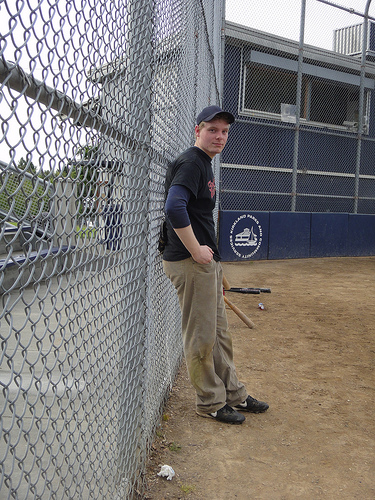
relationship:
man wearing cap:
[162, 106, 272, 423] [193, 102, 236, 125]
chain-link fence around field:
[0, 1, 227, 500] [213, 264, 374, 498]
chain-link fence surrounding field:
[0, 1, 227, 500] [185, 257, 371, 497]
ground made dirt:
[279, 245, 370, 339] [267, 379, 332, 443]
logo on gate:
[226, 211, 265, 260] [218, 19, 373, 269]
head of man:
[190, 104, 231, 154] [162, 106, 272, 423]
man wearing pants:
[162, 106, 272, 423] [166, 258, 245, 412]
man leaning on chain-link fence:
[156, 103, 273, 424] [0, 1, 227, 500]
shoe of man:
[195, 405, 246, 426] [162, 106, 272, 423]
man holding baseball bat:
[162, 106, 272, 423] [217, 294, 258, 330]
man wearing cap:
[162, 106, 272, 423] [196, 102, 237, 121]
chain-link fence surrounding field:
[0, 1, 227, 500] [2, 0, 373, 493]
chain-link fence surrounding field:
[0, 1, 219, 494] [129, 258, 373, 498]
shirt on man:
[157, 144, 221, 261] [162, 106, 272, 423]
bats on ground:
[229, 283, 274, 294] [130, 256, 375, 498]